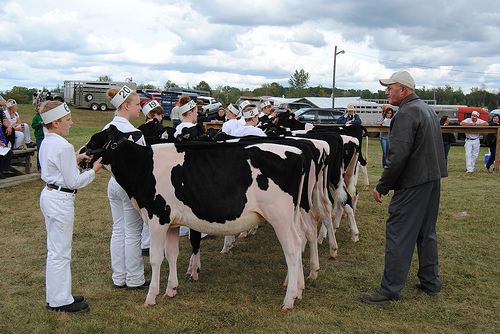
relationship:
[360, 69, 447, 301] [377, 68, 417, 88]
man wearing cap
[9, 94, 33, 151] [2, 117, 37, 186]
person sitting in bleachers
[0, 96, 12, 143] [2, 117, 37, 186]
person sitting in bleachers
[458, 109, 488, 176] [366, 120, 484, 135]
man standing behind table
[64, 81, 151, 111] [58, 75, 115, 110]
vehicle for animal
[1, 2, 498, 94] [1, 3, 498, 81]
cloud in sky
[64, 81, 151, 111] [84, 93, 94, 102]
vehicle has wheel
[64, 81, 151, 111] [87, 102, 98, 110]
vehicle has wheel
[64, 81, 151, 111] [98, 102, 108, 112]
vehicle has wheel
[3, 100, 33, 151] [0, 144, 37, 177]
person on stand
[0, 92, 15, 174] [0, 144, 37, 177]
person on stand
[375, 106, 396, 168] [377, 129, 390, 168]
woman wears blue jeans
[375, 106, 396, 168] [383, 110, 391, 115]
woman wears sunglasses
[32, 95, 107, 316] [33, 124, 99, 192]
boy wears shirt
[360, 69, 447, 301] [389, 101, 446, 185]
man wears jacket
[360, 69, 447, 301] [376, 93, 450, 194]
man wears jacket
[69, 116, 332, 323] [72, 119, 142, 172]
cow has head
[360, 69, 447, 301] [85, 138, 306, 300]
man behind cow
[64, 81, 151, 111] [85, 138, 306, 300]
vehicle transport cow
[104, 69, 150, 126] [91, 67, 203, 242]
head has girl